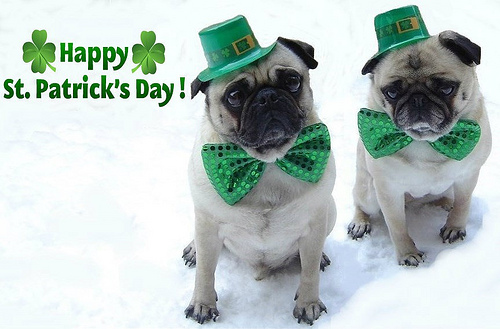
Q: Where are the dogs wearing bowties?
A: Neck.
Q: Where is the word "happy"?
A: Between two clovers.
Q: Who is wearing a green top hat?
A: Both dogs.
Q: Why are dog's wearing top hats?
A: Part of costume.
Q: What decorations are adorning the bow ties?
A: Sequins.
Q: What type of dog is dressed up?
A: Pug.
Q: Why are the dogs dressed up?
A: To celebrate St Patty's Day.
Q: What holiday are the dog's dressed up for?
A: St Patty's Day.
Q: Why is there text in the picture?
A: To wish a happy holiday.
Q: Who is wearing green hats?
A: The two pugs.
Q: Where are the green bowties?
A: Around the dog's necks.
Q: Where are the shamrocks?
A: Around the word "Happy.".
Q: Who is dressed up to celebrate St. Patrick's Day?
A: The two dogs.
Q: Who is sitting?
A: The dogs.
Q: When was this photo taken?
A: After a snowfall.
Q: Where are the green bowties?
A: On the dogs.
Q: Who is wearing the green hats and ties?
A: The two dogs.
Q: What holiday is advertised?
A: St. patrick's day.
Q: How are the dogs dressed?
A: In hats and bowties.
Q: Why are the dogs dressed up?
A: To advertise the holiday.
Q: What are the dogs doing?
A: Sitting down.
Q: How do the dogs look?
A: Bored.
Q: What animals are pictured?
A: Dogs.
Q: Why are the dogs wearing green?
A: For St. Patrick's day.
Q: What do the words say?
A: Happy St. Patrick's Day.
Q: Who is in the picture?
A: No one.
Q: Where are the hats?
A: On the dog's head.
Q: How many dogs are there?
A: 2.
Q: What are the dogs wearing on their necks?
A: Bow ties.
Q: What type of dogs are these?
A: Pugs.